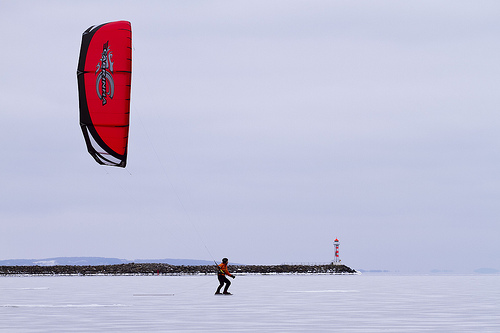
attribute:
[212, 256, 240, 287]
helmet — black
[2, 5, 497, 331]
day — overcast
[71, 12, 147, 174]
parachute — red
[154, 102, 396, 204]
sky — overcast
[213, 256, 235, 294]
waterskier — red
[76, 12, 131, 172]
parachute — red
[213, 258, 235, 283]
jacket — red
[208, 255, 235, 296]
man — wearing orange, wearing black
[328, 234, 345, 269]
lighthouse — brightly colored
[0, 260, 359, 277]
peninsula — rocky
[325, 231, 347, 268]
shirt — white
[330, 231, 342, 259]
light house — sits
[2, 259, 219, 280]
mountain range — distant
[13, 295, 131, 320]
water — ice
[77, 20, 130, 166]
parachute — black, red, gray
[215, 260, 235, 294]
man — parasailing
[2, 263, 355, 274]
rocks — jetting out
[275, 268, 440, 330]
water. — large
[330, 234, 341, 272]
lighthouse — red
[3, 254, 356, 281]
strip — rocky